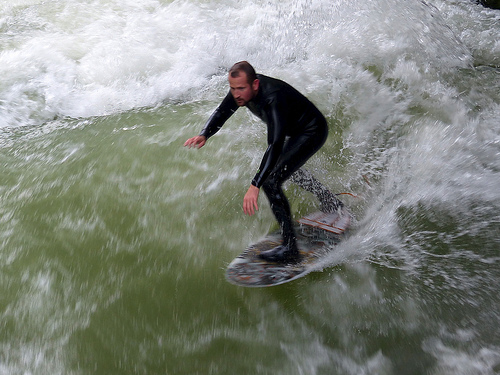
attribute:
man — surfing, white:
[201, 56, 355, 255]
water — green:
[68, 22, 154, 54]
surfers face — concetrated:
[216, 68, 275, 121]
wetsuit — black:
[271, 120, 296, 240]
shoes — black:
[258, 238, 300, 264]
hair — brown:
[236, 65, 254, 73]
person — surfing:
[215, 75, 319, 266]